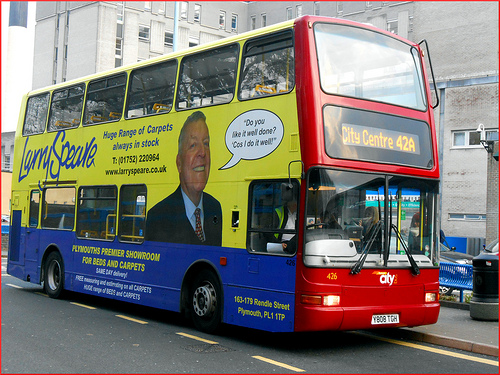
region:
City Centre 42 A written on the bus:
[331, 105, 428, 167]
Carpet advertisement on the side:
[19, 85, 307, 323]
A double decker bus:
[10, 15, 473, 337]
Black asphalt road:
[2, 275, 327, 373]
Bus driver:
[247, 170, 360, 258]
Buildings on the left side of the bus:
[8, 0, 495, 94]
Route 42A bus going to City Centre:
[5, 23, 465, 333]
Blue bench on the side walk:
[433, 259, 478, 302]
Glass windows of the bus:
[8, 20, 295, 327]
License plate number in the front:
[362, 306, 409, 328]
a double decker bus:
[18, 14, 485, 311]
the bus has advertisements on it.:
[10, 120, 304, 204]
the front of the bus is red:
[318, 75, 433, 323]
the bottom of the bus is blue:
[18, 231, 263, 325]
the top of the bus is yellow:
[22, 83, 300, 217]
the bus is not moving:
[10, 54, 444, 324]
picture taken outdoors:
[7, 8, 497, 368]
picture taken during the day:
[12, 11, 490, 372]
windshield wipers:
[354, 215, 412, 277]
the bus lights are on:
[307, 285, 438, 317]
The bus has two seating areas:
[3, 14, 458, 346]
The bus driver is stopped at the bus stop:
[256, 191, 303, 249]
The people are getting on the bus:
[356, 198, 432, 254]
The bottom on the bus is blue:
[6, 230, 298, 325]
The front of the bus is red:
[295, 15, 452, 337]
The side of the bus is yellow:
[8, 17, 301, 244]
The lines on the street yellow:
[87, 302, 342, 374]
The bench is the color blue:
[440, 255, 476, 304]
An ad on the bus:
[144, 103, 282, 247]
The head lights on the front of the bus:
[316, 288, 444, 315]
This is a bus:
[10, 9, 452, 337]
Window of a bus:
[19, 88, 49, 139]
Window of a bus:
[47, 85, 83, 127]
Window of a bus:
[87, 78, 129, 116]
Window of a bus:
[129, 68, 181, 116]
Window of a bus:
[181, 49, 238, 107]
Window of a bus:
[241, 32, 306, 96]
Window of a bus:
[41, 182, 76, 231]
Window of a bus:
[71, 183, 119, 234]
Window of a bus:
[247, 173, 299, 257]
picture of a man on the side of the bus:
[135, 116, 242, 246]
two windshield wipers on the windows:
[344, 215, 432, 292]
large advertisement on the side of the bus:
[9, 18, 304, 340]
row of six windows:
[19, 28, 300, 153]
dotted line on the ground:
[7, 272, 299, 371]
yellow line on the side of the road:
[364, 326, 494, 374]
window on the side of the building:
[112, 33, 128, 58]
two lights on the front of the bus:
[317, 289, 445, 312]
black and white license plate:
[364, 311, 402, 327]